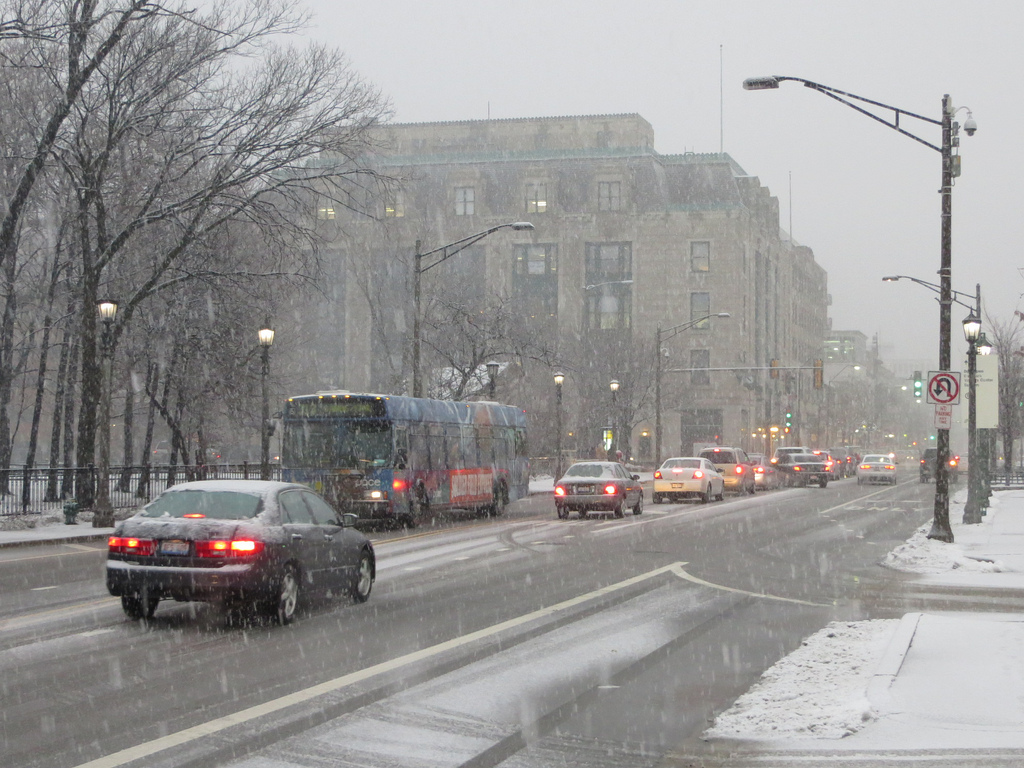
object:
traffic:
[106, 479, 375, 626]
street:
[0, 454, 1024, 768]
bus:
[265, 389, 531, 533]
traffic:
[555, 461, 643, 519]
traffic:
[652, 456, 724, 504]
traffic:
[696, 445, 756, 497]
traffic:
[747, 453, 779, 491]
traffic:
[774, 453, 831, 488]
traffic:
[855, 454, 899, 486]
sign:
[926, 370, 961, 405]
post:
[926, 93, 954, 547]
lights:
[109, 536, 158, 555]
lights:
[195, 539, 264, 557]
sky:
[0, 0, 1024, 380]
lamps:
[742, 76, 778, 90]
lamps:
[510, 221, 537, 230]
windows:
[584, 241, 633, 336]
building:
[250, 112, 831, 474]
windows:
[510, 243, 557, 351]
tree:
[0, 0, 228, 510]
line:
[76, 561, 686, 767]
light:
[914, 371, 922, 397]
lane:
[750, 486, 953, 533]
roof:
[318, 112, 639, 131]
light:
[717, 312, 730, 318]